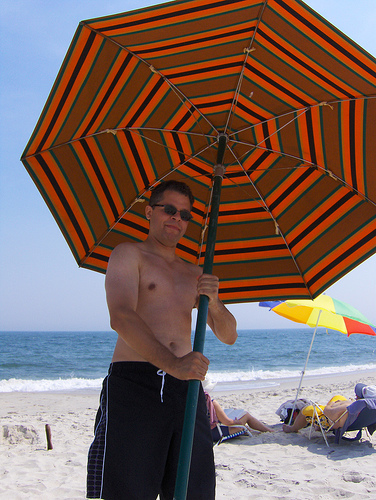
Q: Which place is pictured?
A: It is a beach.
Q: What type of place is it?
A: It is a beach.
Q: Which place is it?
A: It is a beach.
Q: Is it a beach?
A: Yes, it is a beach.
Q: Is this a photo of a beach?
A: Yes, it is showing a beach.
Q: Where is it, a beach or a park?
A: It is a beach.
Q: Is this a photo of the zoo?
A: No, the picture is showing the beach.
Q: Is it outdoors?
A: Yes, it is outdoors.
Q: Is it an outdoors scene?
A: Yes, it is outdoors.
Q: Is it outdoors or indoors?
A: It is outdoors.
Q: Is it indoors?
A: No, it is outdoors.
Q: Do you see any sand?
A: Yes, there is sand.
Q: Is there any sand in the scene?
A: Yes, there is sand.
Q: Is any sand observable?
A: Yes, there is sand.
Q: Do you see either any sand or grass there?
A: Yes, there is sand.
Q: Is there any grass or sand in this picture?
A: Yes, there is sand.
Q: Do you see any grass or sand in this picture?
A: Yes, there is sand.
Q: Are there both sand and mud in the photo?
A: No, there is sand but no mud.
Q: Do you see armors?
A: No, there are no armors.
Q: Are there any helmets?
A: No, there are no helmets.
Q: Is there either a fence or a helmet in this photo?
A: No, there are no helmets or fences.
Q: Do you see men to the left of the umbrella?
A: Yes, there is a man to the left of the umbrella.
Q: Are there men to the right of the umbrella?
A: No, the man is to the left of the umbrella.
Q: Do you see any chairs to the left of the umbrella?
A: No, there is a man to the left of the umbrella.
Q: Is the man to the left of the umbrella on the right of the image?
A: Yes, the man is to the left of the umbrella.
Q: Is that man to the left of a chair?
A: No, the man is to the left of the umbrella.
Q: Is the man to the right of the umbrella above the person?
A: No, the man is to the left of the umbrella.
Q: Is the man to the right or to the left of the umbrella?
A: The man is to the left of the umbrella.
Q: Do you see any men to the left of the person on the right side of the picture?
A: Yes, there is a man to the left of the person.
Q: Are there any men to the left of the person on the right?
A: Yes, there is a man to the left of the person.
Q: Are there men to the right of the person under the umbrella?
A: No, the man is to the left of the person.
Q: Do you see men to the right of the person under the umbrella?
A: No, the man is to the left of the person.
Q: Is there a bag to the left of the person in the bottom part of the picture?
A: No, there is a man to the left of the person.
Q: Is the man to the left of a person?
A: Yes, the man is to the left of a person.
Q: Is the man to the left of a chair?
A: No, the man is to the left of a person.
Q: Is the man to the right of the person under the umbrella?
A: No, the man is to the left of the person.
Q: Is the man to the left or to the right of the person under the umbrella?
A: The man is to the left of the person.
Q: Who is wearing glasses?
A: The man is wearing glasses.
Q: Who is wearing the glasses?
A: The man is wearing glasses.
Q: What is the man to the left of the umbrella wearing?
A: The man is wearing glasses.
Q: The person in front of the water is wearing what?
A: The man is wearing glasses.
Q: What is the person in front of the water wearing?
A: The man is wearing glasses.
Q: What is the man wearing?
A: The man is wearing glasses.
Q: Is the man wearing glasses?
A: Yes, the man is wearing glasses.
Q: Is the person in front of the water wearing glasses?
A: Yes, the man is wearing glasses.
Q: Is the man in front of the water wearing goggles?
A: No, the man is wearing glasses.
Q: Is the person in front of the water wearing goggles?
A: No, the man is wearing glasses.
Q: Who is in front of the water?
A: The man is in front of the water.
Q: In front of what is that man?
A: The man is in front of the water.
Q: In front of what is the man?
A: The man is in front of the water.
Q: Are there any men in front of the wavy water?
A: Yes, there is a man in front of the water.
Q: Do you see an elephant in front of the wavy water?
A: No, there is a man in front of the water.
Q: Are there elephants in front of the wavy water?
A: No, there is a man in front of the water.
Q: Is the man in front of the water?
A: Yes, the man is in front of the water.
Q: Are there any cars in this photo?
A: No, there are no cars.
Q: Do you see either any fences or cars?
A: No, there are no cars or fences.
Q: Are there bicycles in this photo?
A: No, there are no bicycles.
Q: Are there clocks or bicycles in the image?
A: No, there are no bicycles or clocks.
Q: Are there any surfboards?
A: No, there are no surfboards.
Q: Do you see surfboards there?
A: No, there are no surfboards.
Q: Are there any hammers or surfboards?
A: No, there are no surfboards or hammers.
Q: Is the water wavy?
A: Yes, the water is wavy.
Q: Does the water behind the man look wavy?
A: Yes, the water is wavy.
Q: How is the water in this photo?
A: The water is wavy.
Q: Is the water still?
A: No, the water is wavy.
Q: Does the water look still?
A: No, the water is wavy.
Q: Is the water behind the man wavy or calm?
A: The water is wavy.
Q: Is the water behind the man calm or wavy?
A: The water is wavy.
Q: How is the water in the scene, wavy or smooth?
A: The water is wavy.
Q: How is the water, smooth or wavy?
A: The water is wavy.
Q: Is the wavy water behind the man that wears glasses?
A: Yes, the water is behind the man.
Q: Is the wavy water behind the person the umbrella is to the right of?
A: Yes, the water is behind the man.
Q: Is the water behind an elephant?
A: No, the water is behind the man.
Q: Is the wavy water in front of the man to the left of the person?
A: No, the water is behind the man.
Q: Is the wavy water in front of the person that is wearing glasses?
A: No, the water is behind the man.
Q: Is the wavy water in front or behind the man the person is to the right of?
A: The water is behind the man.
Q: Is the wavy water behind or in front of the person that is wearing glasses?
A: The water is behind the man.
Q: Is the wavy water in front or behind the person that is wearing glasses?
A: The water is behind the man.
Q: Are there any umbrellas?
A: Yes, there is an umbrella.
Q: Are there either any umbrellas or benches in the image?
A: Yes, there is an umbrella.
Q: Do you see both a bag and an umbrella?
A: No, there is an umbrella but no bags.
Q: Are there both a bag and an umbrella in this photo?
A: No, there is an umbrella but no bags.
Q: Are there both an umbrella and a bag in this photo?
A: No, there is an umbrella but no bags.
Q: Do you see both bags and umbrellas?
A: No, there is an umbrella but no bags.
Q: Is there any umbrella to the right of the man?
A: Yes, there is an umbrella to the right of the man.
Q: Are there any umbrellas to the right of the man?
A: Yes, there is an umbrella to the right of the man.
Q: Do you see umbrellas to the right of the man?
A: Yes, there is an umbrella to the right of the man.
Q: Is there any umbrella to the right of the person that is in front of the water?
A: Yes, there is an umbrella to the right of the man.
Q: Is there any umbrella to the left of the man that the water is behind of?
A: No, the umbrella is to the right of the man.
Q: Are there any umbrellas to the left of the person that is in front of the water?
A: No, the umbrella is to the right of the man.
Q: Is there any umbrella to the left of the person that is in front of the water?
A: No, the umbrella is to the right of the man.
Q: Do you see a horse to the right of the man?
A: No, there is an umbrella to the right of the man.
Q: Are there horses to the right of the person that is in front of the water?
A: No, there is an umbrella to the right of the man.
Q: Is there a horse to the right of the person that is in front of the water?
A: No, there is an umbrella to the right of the man.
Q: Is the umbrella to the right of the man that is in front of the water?
A: Yes, the umbrella is to the right of the man.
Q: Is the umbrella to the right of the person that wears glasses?
A: Yes, the umbrella is to the right of the man.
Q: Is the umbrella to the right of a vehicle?
A: No, the umbrella is to the right of the man.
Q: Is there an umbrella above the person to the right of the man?
A: Yes, there is an umbrella above the person.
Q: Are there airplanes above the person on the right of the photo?
A: No, there is an umbrella above the person.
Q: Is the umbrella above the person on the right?
A: Yes, the umbrella is above the person.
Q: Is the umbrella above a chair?
A: No, the umbrella is above the person.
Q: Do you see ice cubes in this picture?
A: No, there are no ice cubes.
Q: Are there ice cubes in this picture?
A: No, there are no ice cubes.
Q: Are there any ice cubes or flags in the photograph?
A: No, there are no ice cubes or flags.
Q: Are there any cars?
A: No, there are no cars.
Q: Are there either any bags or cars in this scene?
A: No, there are no cars or bags.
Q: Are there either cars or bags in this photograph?
A: No, there are no cars or bags.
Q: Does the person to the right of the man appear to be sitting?
A: Yes, the person is sitting.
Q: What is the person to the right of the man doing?
A: The person is sitting.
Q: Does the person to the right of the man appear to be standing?
A: No, the person is sitting.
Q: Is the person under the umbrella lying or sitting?
A: The person is sitting.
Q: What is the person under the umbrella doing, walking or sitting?
A: The person is sitting.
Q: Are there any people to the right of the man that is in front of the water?
A: Yes, there is a person to the right of the man.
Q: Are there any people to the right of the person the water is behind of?
A: Yes, there is a person to the right of the man.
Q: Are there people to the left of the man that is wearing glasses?
A: No, the person is to the right of the man.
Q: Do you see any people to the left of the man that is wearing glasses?
A: No, the person is to the right of the man.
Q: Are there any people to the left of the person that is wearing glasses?
A: No, the person is to the right of the man.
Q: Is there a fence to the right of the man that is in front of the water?
A: No, there is a person to the right of the man.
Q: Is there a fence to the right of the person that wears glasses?
A: No, there is a person to the right of the man.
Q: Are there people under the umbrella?
A: Yes, there is a person under the umbrella.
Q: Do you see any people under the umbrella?
A: Yes, there is a person under the umbrella.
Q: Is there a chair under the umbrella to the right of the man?
A: No, there is a person under the umbrella.